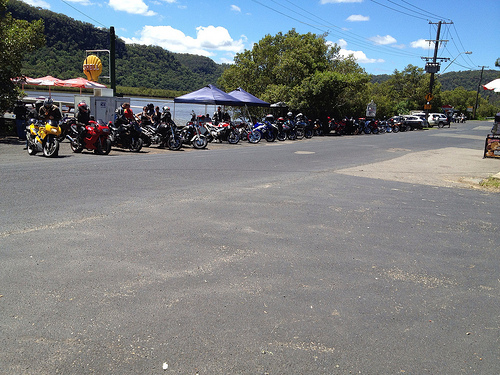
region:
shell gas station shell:
[76, 50, 116, 82]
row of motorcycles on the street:
[23, 81, 400, 173]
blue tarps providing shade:
[167, 76, 294, 154]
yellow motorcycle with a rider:
[17, 93, 68, 170]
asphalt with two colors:
[337, 140, 471, 210]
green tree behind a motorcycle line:
[220, 31, 370, 140]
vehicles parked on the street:
[394, 110, 451, 131]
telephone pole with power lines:
[408, 4, 455, 99]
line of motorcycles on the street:
[23, 88, 391, 162]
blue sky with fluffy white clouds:
[139, 9, 228, 46]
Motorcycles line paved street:
[17, 99, 402, 146]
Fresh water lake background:
[40, 83, 237, 121]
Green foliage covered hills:
[1, 3, 224, 93]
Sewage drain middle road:
[282, 143, 325, 164]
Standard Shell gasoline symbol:
[76, 50, 116, 82]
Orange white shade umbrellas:
[22, 68, 104, 99]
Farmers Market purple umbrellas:
[174, 83, 274, 146]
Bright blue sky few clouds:
[147, 1, 494, 61]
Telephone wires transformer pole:
[412, 11, 472, 96]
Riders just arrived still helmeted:
[32, 97, 116, 159]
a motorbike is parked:
[25, 112, 65, 157]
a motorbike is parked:
[71, 115, 114, 150]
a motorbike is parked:
[113, 115, 149, 150]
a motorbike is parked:
[152, 104, 185, 147]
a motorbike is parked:
[176, 115, 207, 148]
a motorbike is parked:
[221, 117, 246, 147]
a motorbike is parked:
[241, 117, 266, 144]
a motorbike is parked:
[262, 120, 282, 145]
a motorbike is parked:
[271, 118, 293, 142]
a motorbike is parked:
[303, 120, 313, 137]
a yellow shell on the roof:
[79, 50, 107, 85]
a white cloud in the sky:
[122, 19, 244, 56]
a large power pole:
[409, 14, 464, 103]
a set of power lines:
[241, 0, 488, 77]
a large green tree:
[213, 25, 371, 125]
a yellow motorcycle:
[17, 111, 68, 166]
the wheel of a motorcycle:
[37, 136, 64, 161]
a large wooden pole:
[103, 23, 122, 96]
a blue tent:
[173, 77, 242, 116]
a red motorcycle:
[63, 109, 116, 161]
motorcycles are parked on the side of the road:
[18, 90, 411, 157]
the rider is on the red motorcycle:
[62, 100, 115, 159]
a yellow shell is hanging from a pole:
[78, 39, 118, 85]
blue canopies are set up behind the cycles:
[166, 80, 268, 140]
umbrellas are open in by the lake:
[14, 70, 105, 122]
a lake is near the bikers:
[8, 82, 230, 144]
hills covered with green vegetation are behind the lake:
[6, 2, 498, 151]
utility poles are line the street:
[396, 5, 488, 122]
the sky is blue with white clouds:
[40, 4, 499, 75]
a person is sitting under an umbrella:
[481, 75, 498, 159]